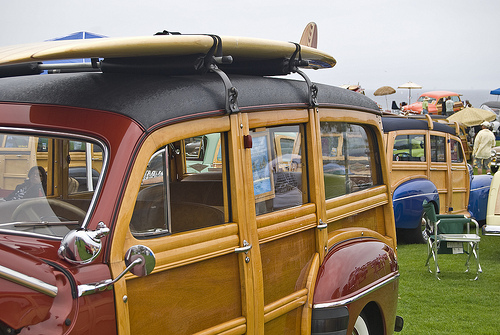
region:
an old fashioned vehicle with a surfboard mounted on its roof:
[1, 10, 431, 331]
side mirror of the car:
[61, 231, 162, 293]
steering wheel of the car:
[12, 200, 92, 240]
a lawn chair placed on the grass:
[419, 196, 486, 290]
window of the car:
[125, 128, 247, 241]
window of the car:
[248, 123, 327, 213]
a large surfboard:
[0, 21, 343, 75]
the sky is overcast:
[344, 5, 496, 81]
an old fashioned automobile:
[384, 111, 499, 230]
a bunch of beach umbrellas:
[358, 81, 498, 112]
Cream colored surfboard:
[2, 15, 339, 82]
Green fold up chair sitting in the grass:
[416, 195, 498, 287]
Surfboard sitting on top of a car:
[2, 14, 418, 334]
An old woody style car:
[0, 10, 418, 332]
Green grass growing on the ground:
[411, 285, 497, 333]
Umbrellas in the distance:
[351, 77, 421, 116]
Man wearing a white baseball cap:
[469, 118, 497, 175]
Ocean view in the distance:
[366, 75, 498, 115]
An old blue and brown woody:
[379, 111, 498, 226]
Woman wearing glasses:
[5, 151, 48, 206]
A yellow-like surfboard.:
[1, 21, 336, 69]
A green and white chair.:
[420, 201, 482, 279]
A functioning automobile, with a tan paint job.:
[375, 111, 495, 231]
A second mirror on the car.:
[120, 241, 151, 271]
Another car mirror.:
[57, 221, 107, 263]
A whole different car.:
[0, 70, 398, 333]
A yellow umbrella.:
[372, 83, 397, 95]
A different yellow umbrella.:
[396, 78, 422, 89]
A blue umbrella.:
[488, 83, 498, 91]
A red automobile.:
[403, 91, 468, 118]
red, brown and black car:
[1, 62, 406, 332]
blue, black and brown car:
[376, 112, 493, 235]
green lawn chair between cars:
[418, 197, 483, 284]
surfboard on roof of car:
[0, 20, 337, 71]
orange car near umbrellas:
[401, 90, 467, 120]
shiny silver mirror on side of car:
[123, 245, 157, 277]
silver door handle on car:
[231, 240, 251, 260]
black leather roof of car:
[1, 76, 380, 131]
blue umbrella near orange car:
[488, 89, 498, 94]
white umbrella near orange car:
[399, 80, 422, 96]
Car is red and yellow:
[3, 33, 418, 333]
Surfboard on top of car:
[0, 12, 350, 77]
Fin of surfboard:
[293, 14, 321, 46]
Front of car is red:
[1, 101, 136, 333]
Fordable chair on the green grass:
[413, 191, 493, 293]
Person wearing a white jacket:
[466, 114, 499, 184]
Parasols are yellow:
[341, 63, 426, 101]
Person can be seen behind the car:
[8, 158, 54, 205]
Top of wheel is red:
[315, 238, 405, 329]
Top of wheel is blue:
[388, 175, 444, 232]